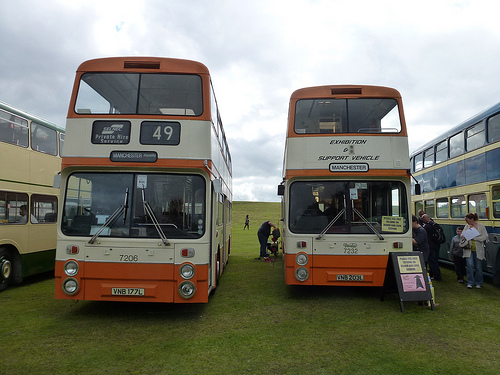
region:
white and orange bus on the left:
[51, 53, 234, 306]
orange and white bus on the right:
[276, 83, 414, 290]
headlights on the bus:
[294, 250, 311, 285]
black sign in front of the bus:
[379, 249, 439, 317]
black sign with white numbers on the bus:
[135, 117, 184, 148]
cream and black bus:
[1, 97, 67, 290]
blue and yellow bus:
[408, 99, 499, 286]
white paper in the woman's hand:
[461, 225, 481, 241]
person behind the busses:
[241, 211, 253, 229]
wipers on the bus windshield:
[86, 183, 175, 248]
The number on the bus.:
[142, 122, 184, 147]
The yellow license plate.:
[108, 286, 149, 297]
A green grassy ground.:
[0, 316, 497, 373]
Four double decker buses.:
[0, 55, 497, 310]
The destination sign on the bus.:
[327, 162, 371, 172]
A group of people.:
[413, 202, 496, 289]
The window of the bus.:
[58, 172, 205, 242]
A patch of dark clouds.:
[0, 0, 62, 90]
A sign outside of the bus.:
[386, 248, 440, 314]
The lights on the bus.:
[288, 250, 312, 284]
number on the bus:
[148, 122, 173, 142]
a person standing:
[465, 213, 490, 282]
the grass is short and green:
[226, 264, 286, 366]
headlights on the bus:
[175, 265, 201, 297]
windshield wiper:
[136, 189, 173, 242]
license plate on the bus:
[109, 285, 151, 300]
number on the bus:
[110, 253, 147, 265]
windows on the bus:
[3, 195, 51, 223]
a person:
[256, 207, 277, 257]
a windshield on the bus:
[74, 73, 199, 125]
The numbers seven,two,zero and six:
[114, 249, 141, 264]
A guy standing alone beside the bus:
[258, 218, 283, 267]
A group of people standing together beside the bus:
[414, 208, 484, 288]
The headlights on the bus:
[294, 253, 308, 281]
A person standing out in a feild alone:
[241, 212, 251, 229]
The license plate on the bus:
[337, 275, 368, 283]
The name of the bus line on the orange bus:
[319, 138, 381, 163]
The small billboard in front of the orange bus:
[386, 252, 428, 314]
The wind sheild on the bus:
[294, 184, 404, 234]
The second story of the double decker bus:
[87, 60, 207, 122]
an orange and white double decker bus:
[35, 37, 220, 315]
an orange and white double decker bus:
[276, 71, 421, 294]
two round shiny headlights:
[57, 257, 82, 304]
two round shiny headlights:
[171, 257, 202, 304]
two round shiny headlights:
[283, 241, 325, 289]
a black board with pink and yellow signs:
[389, 250, 441, 315]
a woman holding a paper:
[456, 197, 498, 293]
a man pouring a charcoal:
[244, 211, 288, 264]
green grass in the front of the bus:
[218, 307, 398, 374]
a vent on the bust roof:
[321, 80, 368, 98]